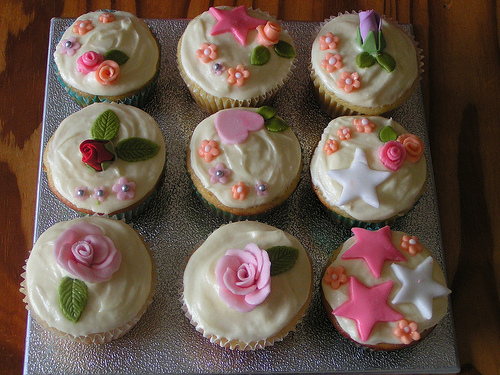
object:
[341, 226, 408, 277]
star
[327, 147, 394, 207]
star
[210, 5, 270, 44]
star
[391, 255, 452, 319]
star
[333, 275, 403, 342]
star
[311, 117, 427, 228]
cupcake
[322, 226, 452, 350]
cupcake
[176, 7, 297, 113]
cupcake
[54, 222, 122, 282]
rose designs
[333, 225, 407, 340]
two stars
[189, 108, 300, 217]
cupcake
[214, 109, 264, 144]
heart design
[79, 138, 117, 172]
rose design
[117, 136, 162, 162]
leaves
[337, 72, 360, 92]
floral design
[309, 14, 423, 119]
cupcake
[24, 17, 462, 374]
tray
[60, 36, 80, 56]
pink flower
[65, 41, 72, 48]
silver bead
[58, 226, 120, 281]
rose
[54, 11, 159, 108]
cupcake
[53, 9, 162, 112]
wrapper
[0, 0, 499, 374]
table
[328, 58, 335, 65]
pearl centers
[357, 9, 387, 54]
rose bud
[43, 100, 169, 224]
cupcake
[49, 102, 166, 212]
icing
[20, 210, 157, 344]
cupcake